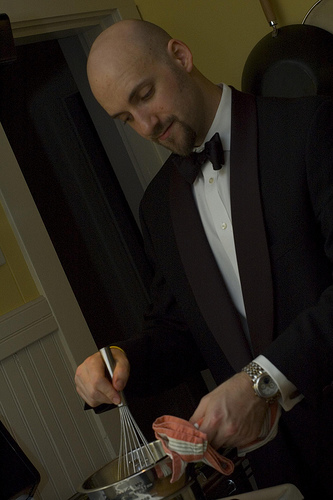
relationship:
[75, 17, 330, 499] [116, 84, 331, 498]
man in tux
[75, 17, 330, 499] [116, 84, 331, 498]
man wearing tuxedo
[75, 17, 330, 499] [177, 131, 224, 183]
man wearing bowtie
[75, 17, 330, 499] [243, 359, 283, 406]
man wearing watch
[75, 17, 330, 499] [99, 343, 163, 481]
man using a whisk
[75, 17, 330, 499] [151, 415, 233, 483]
man using kitchen towel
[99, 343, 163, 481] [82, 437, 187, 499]
whisk in bowl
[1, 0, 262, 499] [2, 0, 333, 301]
doorway in background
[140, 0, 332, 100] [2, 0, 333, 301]
wall in background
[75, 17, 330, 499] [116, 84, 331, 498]
man in tuxedo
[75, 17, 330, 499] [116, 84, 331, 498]
man in a tuxedo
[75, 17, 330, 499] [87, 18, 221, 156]
man has a head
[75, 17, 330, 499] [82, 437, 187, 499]
man mixing in a pot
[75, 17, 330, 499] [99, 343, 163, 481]
man holding whisk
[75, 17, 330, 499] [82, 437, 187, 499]
man holding pot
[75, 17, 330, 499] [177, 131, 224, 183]
man wearing a bowtie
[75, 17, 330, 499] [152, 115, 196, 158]
man has a goatee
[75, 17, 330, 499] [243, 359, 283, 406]
man wearing a wristwatch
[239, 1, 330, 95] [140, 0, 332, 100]
pan on wall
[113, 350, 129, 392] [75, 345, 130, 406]
thumb of hand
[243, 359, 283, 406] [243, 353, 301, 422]
watch on a wrist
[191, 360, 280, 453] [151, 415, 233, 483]
hand holding kitchen towel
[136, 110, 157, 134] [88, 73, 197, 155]
nose on face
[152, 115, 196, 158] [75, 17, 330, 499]
beard on man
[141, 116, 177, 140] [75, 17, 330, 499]
mustache of man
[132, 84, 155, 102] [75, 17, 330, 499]
eye of man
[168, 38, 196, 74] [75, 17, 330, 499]
ear of man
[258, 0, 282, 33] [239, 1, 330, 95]
handle of pan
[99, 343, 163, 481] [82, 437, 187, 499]
utensil in bowl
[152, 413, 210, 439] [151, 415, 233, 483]
orange and white kitchen towel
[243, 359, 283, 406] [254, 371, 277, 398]
silver watch face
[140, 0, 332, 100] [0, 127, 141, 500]
wall with lines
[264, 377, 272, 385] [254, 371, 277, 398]
circles on face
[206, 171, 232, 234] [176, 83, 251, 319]
buttons on shirt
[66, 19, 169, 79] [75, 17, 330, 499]
bald headed man